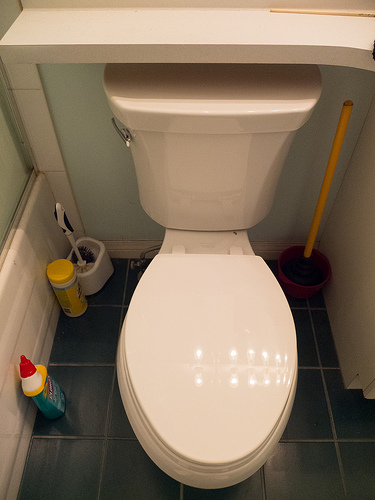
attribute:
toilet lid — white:
[118, 252, 297, 466]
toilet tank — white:
[100, 61, 327, 230]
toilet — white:
[76, 66, 311, 498]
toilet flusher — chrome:
[109, 114, 132, 152]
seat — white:
[120, 240, 305, 459]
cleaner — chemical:
[43, 256, 88, 318]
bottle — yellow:
[46, 258, 87, 317]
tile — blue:
[280, 443, 347, 498]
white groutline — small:
[94, 261, 135, 481]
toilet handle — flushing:
[110, 116, 131, 145]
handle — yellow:
[301, 98, 356, 259]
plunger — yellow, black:
[282, 247, 318, 286]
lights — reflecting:
[174, 345, 303, 395]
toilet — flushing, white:
[102, 63, 326, 487]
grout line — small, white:
[28, 432, 135, 441]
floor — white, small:
[17, 257, 374, 498]